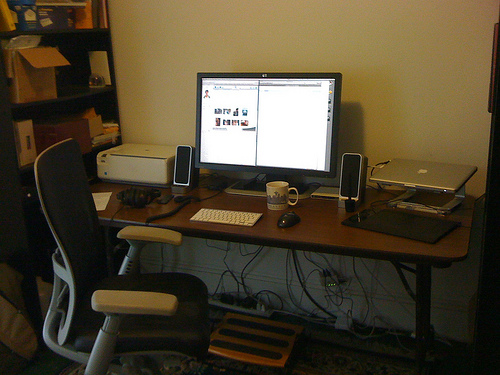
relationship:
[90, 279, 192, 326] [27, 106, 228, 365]
armrest of chair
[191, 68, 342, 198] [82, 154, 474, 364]
monitor on a table